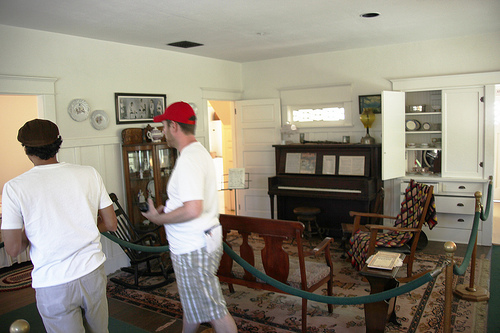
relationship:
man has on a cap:
[140, 100, 241, 332] [153, 101, 197, 125]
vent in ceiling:
[146, 37, 206, 50] [254, 6, 333, 42]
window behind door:
[291, 104, 345, 126] [234, 98, 283, 218]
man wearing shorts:
[140, 100, 241, 332] [165, 244, 225, 326]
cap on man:
[153, 101, 197, 125] [140, 100, 241, 332]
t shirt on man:
[1, 160, 113, 290] [0, 120, 121, 333]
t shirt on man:
[161, 140, 223, 257] [140, 100, 241, 332]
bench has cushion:
[217, 213, 336, 331] [228, 249, 330, 290]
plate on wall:
[90, 108, 110, 130] [2, 25, 240, 212]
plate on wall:
[64, 95, 91, 124] [2, 25, 240, 212]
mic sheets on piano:
[282, 150, 367, 178] [266, 137, 381, 240]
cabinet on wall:
[445, 93, 479, 180] [256, 37, 496, 219]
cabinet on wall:
[381, 86, 432, 174] [256, 37, 496, 219]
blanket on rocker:
[365, 184, 420, 241] [343, 174, 436, 282]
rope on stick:
[220, 245, 449, 302] [444, 254, 454, 331]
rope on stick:
[220, 245, 449, 302] [465, 188, 480, 290]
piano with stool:
[266, 137, 381, 240] [292, 206, 320, 236]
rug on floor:
[329, 314, 356, 331] [470, 315, 497, 332]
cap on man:
[144, 97, 198, 129] [140, 100, 241, 332]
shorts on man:
[168, 239, 230, 322] [140, 100, 241, 332]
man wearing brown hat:
[4, 128, 118, 329] [15, 121, 65, 146]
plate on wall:
[67, 98, 92, 123] [3, 22, 498, 285]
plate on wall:
[90, 110, 111, 130] [60, 37, 168, 128]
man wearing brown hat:
[0, 120, 121, 333] [17, 119, 60, 146]